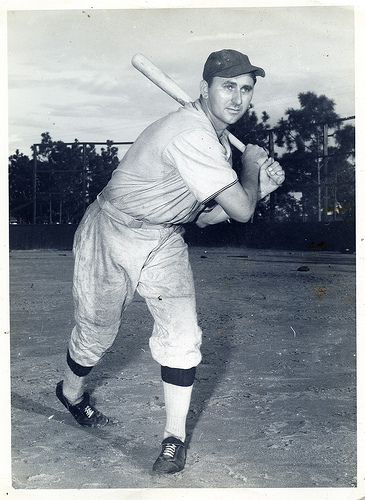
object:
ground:
[9, 246, 355, 488]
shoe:
[55, 377, 107, 429]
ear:
[199, 78, 208, 101]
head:
[199, 49, 256, 124]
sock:
[163, 379, 193, 443]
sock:
[61, 361, 87, 407]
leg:
[136, 227, 202, 438]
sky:
[7, 10, 354, 166]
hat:
[202, 49, 264, 82]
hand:
[259, 157, 286, 197]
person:
[55, 48, 285, 475]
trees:
[271, 91, 343, 222]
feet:
[151, 432, 184, 475]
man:
[55, 49, 284, 475]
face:
[209, 74, 254, 126]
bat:
[130, 53, 284, 186]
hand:
[239, 143, 268, 166]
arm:
[162, 130, 259, 222]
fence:
[30, 115, 354, 224]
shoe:
[151, 436, 187, 474]